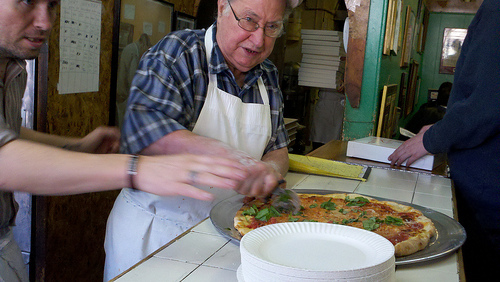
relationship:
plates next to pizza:
[240, 220, 396, 279] [262, 181, 426, 249]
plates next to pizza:
[240, 220, 396, 279] [236, 188, 439, 258]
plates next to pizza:
[230, 215, 406, 279] [234, 186, 434, 251]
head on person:
[213, 2, 294, 72] [130, 1, 287, 198]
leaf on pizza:
[334, 210, 380, 233] [245, 179, 449, 276]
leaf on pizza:
[363, 216, 380, 231] [232, 192, 432, 254]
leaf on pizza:
[383, 214, 402, 224] [232, 192, 432, 254]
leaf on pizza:
[320, 200, 335, 210] [232, 192, 432, 254]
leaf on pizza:
[254, 205, 274, 223] [232, 192, 432, 254]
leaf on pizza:
[241, 205, 258, 216] [232, 192, 432, 254]